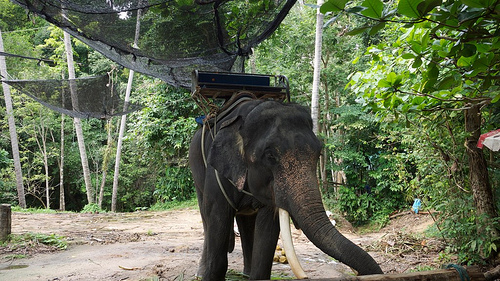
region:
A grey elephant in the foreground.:
[166, 60, 330, 278]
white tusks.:
[278, 212, 299, 277]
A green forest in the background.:
[40, 20, 465, 185]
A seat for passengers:
[185, 60, 297, 95]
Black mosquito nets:
[15, 66, 145, 136]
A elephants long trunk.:
[310, 206, 335, 266]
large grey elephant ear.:
[206, 125, 241, 190]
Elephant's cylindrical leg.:
[251, 212, 276, 267]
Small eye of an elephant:
[262, 150, 274, 160]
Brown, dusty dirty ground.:
[67, 221, 148, 277]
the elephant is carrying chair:
[173, 50, 384, 227]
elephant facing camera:
[189, 92, 384, 278]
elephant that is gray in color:
[188, 94, 382, 279]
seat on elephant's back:
[189, 70, 290, 122]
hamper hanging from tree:
[15, 0, 297, 86]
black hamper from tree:
[17, 0, 299, 90]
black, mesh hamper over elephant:
[18, 0, 297, 90]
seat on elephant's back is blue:
[193, 69, 287, 114]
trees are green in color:
[0, 0, 497, 266]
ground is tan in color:
[0, 202, 443, 277]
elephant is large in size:
[187, 97, 382, 277]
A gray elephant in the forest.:
[176, 92, 383, 279]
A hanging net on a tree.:
[5, 60, 149, 125]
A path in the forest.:
[42, 211, 187, 276]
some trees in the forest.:
[135, 117, 187, 201]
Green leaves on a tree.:
[387, 14, 432, 61]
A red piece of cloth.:
[472, 127, 499, 157]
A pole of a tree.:
[75, 133, 104, 200]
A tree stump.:
[2, 202, 14, 245]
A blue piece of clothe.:
[410, 194, 421, 221]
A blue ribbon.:
[442, 259, 470, 278]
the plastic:
[395, 185, 435, 240]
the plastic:
[405, 200, 430, 210]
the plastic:
[410, 176, 445, 233]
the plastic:
[400, 156, 440, 251]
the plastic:
[400, 187, 421, 208]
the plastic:
[413, 182, 429, 214]